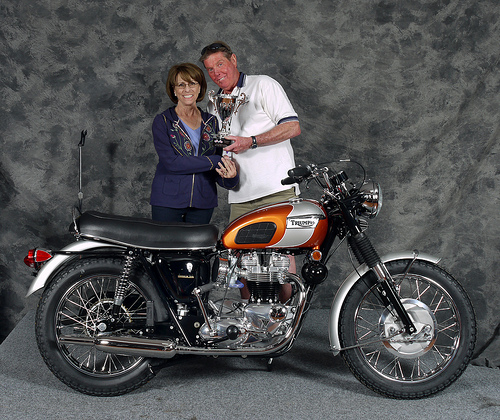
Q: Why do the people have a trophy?
A: They won a competition.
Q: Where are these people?
A: At a photoshoot.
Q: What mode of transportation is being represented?
A: Motorcycle.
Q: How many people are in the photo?
A: Two.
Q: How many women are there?
A: One.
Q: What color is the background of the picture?
A: Grey.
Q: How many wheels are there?
A: Two.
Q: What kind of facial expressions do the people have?
A: Smiles.